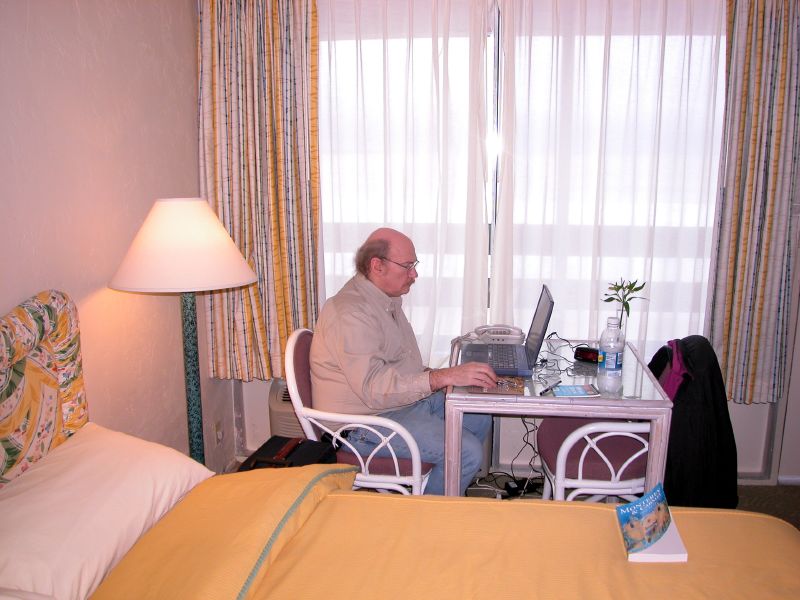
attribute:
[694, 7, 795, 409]
curtain — white, yellow, blue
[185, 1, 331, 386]
curtain panel — yellow, blue, white